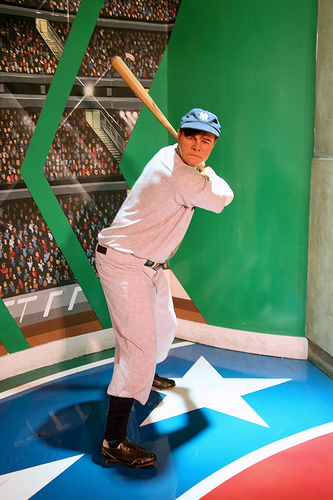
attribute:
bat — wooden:
[104, 51, 186, 153]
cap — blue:
[180, 107, 222, 136]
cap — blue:
[181, 102, 218, 132]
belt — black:
[88, 233, 174, 279]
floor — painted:
[0, 335, 331, 498]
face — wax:
[178, 128, 217, 167]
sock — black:
[106, 394, 132, 444]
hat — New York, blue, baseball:
[179, 107, 224, 138]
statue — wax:
[44, 56, 247, 470]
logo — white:
[197, 110, 208, 121]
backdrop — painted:
[0, 0, 183, 299]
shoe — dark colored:
[97, 434, 158, 469]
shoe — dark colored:
[152, 370, 177, 388]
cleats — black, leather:
[99, 438, 157, 468]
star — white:
[94, 314, 287, 491]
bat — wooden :
[109, 54, 178, 143]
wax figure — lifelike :
[92, 54, 233, 468]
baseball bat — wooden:
[108, 54, 183, 142]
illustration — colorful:
[0, 3, 181, 296]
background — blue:
[2, 351, 322, 496]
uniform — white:
[95, 144, 226, 406]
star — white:
[140, 356, 291, 428]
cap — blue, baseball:
[178, 107, 221, 138]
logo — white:
[199, 112, 210, 119]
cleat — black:
[101, 435, 157, 465]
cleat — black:
[154, 373, 173, 386]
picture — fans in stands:
[3, 1, 179, 297]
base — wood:
[3, 308, 309, 378]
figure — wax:
[92, 52, 233, 466]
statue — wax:
[102, 118, 204, 427]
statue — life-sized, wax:
[106, 110, 208, 430]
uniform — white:
[119, 155, 190, 422]